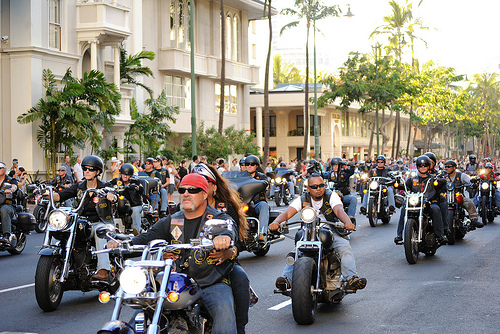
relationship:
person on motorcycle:
[146, 175, 237, 301] [102, 222, 247, 332]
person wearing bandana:
[146, 175, 237, 301] [177, 172, 208, 194]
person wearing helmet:
[55, 161, 96, 208] [82, 162, 99, 172]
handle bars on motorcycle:
[101, 221, 218, 254] [102, 222, 247, 332]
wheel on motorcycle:
[32, 249, 70, 304] [32, 185, 128, 299]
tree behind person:
[329, 59, 415, 158] [146, 175, 237, 301]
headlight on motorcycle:
[105, 263, 159, 294] [102, 222, 247, 332]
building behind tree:
[250, 85, 453, 163] [329, 59, 415, 158]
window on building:
[296, 114, 321, 134] [250, 85, 453, 163]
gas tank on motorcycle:
[183, 308, 207, 333] [102, 222, 247, 332]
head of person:
[170, 171, 211, 212] [146, 175, 237, 301]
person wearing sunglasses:
[146, 175, 237, 301] [174, 187, 201, 195]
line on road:
[266, 284, 297, 318] [4, 167, 498, 333]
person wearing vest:
[146, 175, 237, 301] [163, 213, 232, 282]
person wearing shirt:
[281, 179, 356, 294] [284, 189, 346, 228]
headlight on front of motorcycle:
[105, 263, 159, 294] [102, 222, 247, 332]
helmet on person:
[82, 162, 99, 172] [55, 161, 96, 208]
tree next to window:
[329, 59, 415, 158] [296, 114, 321, 134]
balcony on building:
[289, 117, 323, 144] [250, 85, 453, 163]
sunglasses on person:
[174, 187, 201, 195] [146, 175, 237, 301]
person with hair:
[195, 157, 267, 322] [212, 166, 251, 241]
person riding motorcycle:
[146, 175, 237, 301] [102, 222, 247, 332]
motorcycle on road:
[102, 222, 247, 332] [4, 167, 498, 333]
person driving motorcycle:
[146, 175, 237, 301] [102, 222, 247, 332]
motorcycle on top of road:
[102, 222, 247, 332] [4, 167, 498, 333]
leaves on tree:
[358, 64, 407, 103] [329, 59, 415, 158]